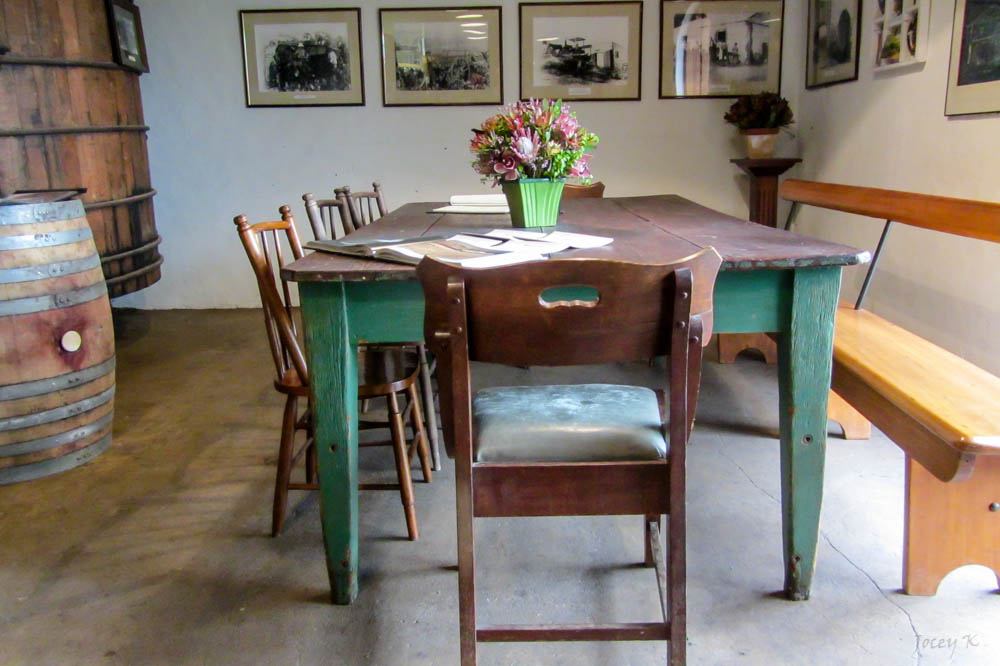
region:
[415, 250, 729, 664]
wooden brown chair with white cushion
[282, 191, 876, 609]
dining table painted brown and green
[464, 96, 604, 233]
bouquet of flowers in a green vase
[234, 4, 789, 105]
four photographs on a wall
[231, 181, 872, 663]
dining table with four chairs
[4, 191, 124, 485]
brown wooden keg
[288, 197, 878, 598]
papers on a wooden table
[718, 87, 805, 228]
flowers on a pedestal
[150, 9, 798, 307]
four pictures on a white wall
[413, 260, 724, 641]
Brown wood chair pushed up to table.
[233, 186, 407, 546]
Brown wood chair pushed up to table.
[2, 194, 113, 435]
Brown barrel sitting on ground.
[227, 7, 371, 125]
Framed picture hanging on wall.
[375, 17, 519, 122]
Framed picture hanging on wall.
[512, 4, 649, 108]
Framed picture hanging on wall.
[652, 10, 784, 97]
Framed picture hanging on wall.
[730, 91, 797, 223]
Plant in pot sitting on wood stand.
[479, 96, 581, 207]
Flowers in pot on table.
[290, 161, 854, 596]
table with green legs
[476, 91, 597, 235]
flower arrangement on the table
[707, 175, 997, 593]
wood bench next to table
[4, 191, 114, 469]
wood barrel with silver stripes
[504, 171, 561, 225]
green vase the flowers are in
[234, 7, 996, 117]
pictures hanging on the wall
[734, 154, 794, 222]
pedestal in the corner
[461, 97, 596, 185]
pink flowers in the green vase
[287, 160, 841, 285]
unpainted wood top on the table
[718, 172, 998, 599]
A long wood bench seat.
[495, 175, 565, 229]
A green planter on the table.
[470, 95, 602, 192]
A pink and green bouquet of flowers.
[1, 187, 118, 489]
A brown and silver barrel with white circle on the front.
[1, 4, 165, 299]
A very large brown barrel off the ground.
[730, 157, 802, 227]
Tall brown plant stand in the corner.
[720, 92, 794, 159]
Flower arrangement on a plant stand in the corner.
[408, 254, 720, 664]
Darkest brown chair at the end of a table.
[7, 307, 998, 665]
A grey and brown concrete floor.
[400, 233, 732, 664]
the chair on front the table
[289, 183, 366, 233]
the chair on front the table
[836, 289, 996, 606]
a bench color brown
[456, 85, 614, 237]
the pot is green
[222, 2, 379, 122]
a picture on the wall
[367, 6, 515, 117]
a picture on the wall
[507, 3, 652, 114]
a picture on the wall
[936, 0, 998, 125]
a picture on the wall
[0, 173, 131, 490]
the barrel is big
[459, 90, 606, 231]
flowers are on table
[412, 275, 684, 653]
chair is made of wood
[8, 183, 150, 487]
barrel is made of wood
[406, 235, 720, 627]
back of a wooden chair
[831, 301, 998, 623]
a long wooden bench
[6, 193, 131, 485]
a large whiskey barrel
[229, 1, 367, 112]
picture on the wall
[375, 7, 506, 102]
picture on the wall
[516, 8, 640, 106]
picture on the wall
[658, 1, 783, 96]
picture on the wall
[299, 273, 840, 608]
base of table is green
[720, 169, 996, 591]
bench seat along the side of table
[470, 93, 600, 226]
flowers on the table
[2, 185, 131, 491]
barrel is made of wood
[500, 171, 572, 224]
flower holder is green